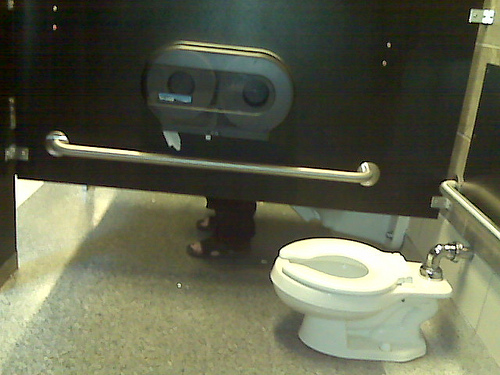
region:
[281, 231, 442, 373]
White toilet in public restroom.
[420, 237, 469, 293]
Silver piping for toilet.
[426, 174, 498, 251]
Silver handi-capped bar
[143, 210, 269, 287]
Persons feet with sandals.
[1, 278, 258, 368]
Gray and white floor.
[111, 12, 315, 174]
Double toilet paper rolls.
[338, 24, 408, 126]
Metal screws on black wall.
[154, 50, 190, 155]
White piece of toilet paper.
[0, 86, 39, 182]
metal plates and screws .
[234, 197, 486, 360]
Toilet in a bathroom.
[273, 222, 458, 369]
the toilet is small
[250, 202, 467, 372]
the toilet is white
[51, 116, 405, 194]
the pole is metal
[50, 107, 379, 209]
the metal is silver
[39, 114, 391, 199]
the railing is long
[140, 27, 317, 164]
the dispenser is black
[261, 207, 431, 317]
the lid is down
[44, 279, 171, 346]
the floor is multi colored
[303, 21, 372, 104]
the wall is black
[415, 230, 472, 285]
the pipes are metal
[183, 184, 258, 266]
The legs of the person in the stall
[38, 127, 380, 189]
The hand rail on the stall's black wall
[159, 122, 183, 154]
The reachable toilet paper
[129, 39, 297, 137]
The toilet paper rolls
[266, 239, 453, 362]
The toilet bowl in the same stall as photographer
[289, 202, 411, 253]
The toilet in the other stall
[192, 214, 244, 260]
The sandals of the person in the stall nextdoor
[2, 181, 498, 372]
The floor of the bathroom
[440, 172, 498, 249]
The rail behind the toilet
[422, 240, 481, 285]
The silver pipe connected to toilet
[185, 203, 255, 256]
this are legs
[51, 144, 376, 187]
this is a metallic rod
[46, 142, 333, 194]
the rod is shiny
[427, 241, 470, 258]
this is a water pipe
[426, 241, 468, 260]
the water pipe is silver in color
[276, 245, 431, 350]
this is a toilet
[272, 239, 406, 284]
this is a toilet seat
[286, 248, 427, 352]
the toilet is white in color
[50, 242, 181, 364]
this is the floor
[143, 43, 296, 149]
this is toilet paper dispenser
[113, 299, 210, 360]
floor of a toilet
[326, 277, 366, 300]
lid of a toilet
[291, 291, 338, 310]
edge of a toilet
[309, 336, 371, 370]
base of a toilet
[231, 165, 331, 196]
part of a metal handle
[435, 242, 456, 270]
part of a metal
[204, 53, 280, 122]
cover of some tissues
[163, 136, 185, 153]
part of a tissue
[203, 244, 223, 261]
part of an open shoe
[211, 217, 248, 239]
end of a trouser